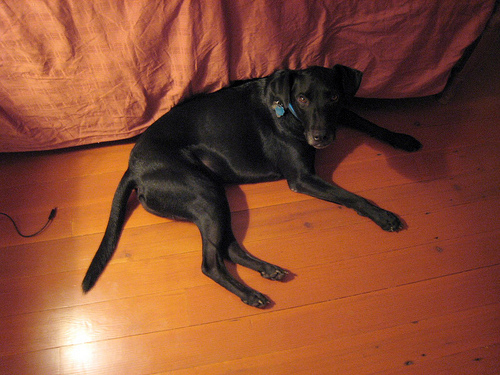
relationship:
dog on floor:
[251, 75, 339, 158] [331, 253, 403, 311]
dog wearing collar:
[251, 75, 339, 158] [279, 100, 293, 121]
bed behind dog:
[145, 14, 199, 47] [251, 75, 339, 158]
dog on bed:
[251, 75, 339, 158] [145, 14, 199, 47]